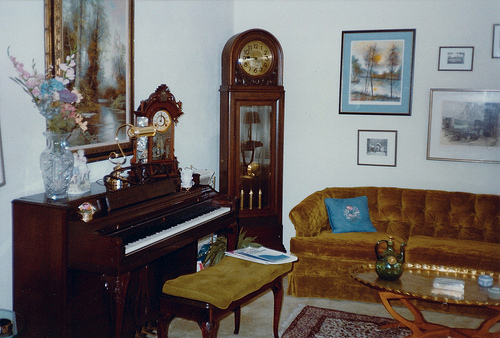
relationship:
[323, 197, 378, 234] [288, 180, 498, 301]
pillow sitting on couch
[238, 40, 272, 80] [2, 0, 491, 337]
clock sitting in room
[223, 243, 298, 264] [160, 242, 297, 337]
paper sitting on bench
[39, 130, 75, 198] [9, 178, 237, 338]
vase sitting on piano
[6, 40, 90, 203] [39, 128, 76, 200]
flowers in pot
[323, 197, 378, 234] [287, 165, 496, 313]
pillow on couch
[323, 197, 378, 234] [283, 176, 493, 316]
pillow on couch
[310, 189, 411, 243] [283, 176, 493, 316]
pillow on couch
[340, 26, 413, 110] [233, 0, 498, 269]
picture on wall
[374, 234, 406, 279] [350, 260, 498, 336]
figurine on coffee table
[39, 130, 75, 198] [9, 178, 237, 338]
vase on piano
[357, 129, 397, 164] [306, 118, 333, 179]
picture on wall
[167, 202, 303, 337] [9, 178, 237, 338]
bench next piano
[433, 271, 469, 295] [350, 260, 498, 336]
paper on coffee table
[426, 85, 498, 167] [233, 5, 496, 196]
picture on wall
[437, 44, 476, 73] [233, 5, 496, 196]
picture on wall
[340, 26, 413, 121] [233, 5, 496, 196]
picture on wall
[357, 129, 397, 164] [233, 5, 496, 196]
picture on wall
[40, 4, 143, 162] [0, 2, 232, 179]
picture on wall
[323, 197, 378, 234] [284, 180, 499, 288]
pillow on couch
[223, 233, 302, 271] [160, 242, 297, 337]
paper on bench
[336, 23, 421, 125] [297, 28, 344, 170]
painting on wall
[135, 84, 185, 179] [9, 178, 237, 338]
clock on piano